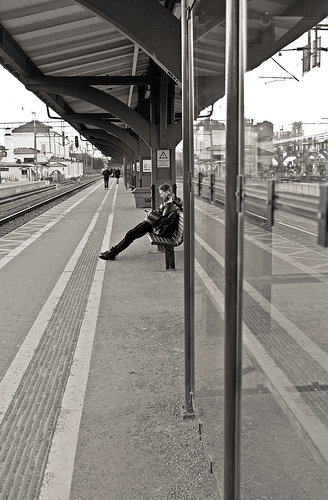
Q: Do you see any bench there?
A: Yes, there is a bench.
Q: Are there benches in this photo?
A: Yes, there is a bench.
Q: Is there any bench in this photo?
A: Yes, there is a bench.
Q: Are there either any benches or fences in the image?
A: Yes, there is a bench.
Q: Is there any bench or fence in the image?
A: Yes, there is a bench.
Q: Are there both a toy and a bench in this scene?
A: No, there is a bench but no toys.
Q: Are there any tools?
A: No, there are no tools.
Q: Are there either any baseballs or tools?
A: No, there are no tools or baseballs.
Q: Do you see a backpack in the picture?
A: Yes, there is a backpack.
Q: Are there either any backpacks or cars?
A: Yes, there is a backpack.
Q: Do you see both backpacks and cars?
A: No, there is a backpack but no cars.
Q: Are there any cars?
A: No, there are no cars.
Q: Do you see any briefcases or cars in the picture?
A: No, there are no cars or briefcases.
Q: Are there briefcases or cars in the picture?
A: No, there are no cars or briefcases.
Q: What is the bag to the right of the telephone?
A: The bag is a backpack.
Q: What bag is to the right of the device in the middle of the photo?
A: The bag is a backpack.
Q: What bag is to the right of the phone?
A: The bag is a backpack.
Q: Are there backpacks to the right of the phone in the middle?
A: Yes, there is a backpack to the right of the phone.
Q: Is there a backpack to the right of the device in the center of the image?
A: Yes, there is a backpack to the right of the phone.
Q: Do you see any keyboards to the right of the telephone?
A: No, there is a backpack to the right of the telephone.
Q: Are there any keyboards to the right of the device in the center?
A: No, there is a backpack to the right of the telephone.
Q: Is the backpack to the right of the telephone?
A: Yes, the backpack is to the right of the telephone.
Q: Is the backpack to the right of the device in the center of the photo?
A: Yes, the backpack is to the right of the telephone.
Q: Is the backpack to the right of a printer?
A: No, the backpack is to the right of the telephone.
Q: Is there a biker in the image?
A: No, there are no bikers.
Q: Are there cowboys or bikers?
A: No, there are no bikers or cowboys.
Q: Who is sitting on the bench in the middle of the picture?
A: The man is sitting on the bench.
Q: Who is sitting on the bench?
A: The man is sitting on the bench.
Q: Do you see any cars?
A: No, there are no cars.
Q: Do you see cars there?
A: No, there are no cars.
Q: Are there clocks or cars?
A: No, there are no cars or clocks.